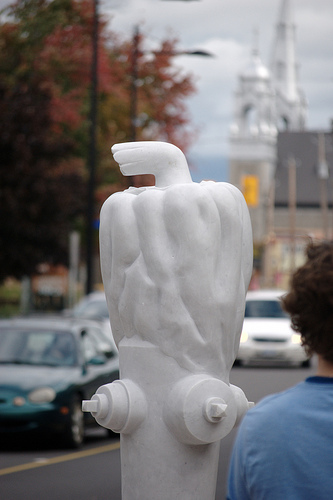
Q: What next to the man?
A: A statue.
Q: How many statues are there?
A: One.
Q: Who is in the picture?
A: A man.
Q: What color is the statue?
A: White.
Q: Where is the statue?
A: By the road.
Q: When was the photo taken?
A: During the day.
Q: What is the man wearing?
A: During the day.